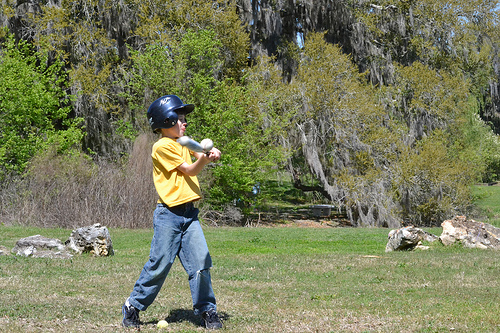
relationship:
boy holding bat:
[123, 94, 223, 331] [178, 136, 216, 162]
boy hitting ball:
[123, 94, 223, 331] [200, 138, 214, 153]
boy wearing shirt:
[123, 94, 223, 331] [151, 137, 204, 208]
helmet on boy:
[147, 96, 195, 134] [123, 94, 223, 331]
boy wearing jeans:
[123, 94, 223, 331] [127, 203, 217, 316]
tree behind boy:
[1, 27, 89, 178] [123, 94, 223, 331]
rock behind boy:
[71, 223, 114, 256] [123, 94, 223, 331]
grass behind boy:
[6, 277, 118, 333] [123, 94, 223, 331]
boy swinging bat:
[123, 94, 223, 331] [178, 136, 216, 162]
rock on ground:
[71, 223, 114, 256] [0, 226, 499, 333]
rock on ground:
[15, 234, 69, 259] [0, 226, 499, 333]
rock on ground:
[440, 215, 499, 249] [0, 226, 499, 333]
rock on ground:
[385, 225, 439, 251] [0, 226, 499, 333]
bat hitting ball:
[178, 136, 216, 162] [200, 138, 214, 153]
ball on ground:
[157, 319, 168, 328] [0, 226, 499, 333]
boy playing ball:
[123, 94, 223, 331] [200, 138, 214, 153]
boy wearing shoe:
[123, 94, 223, 331] [201, 311, 224, 331]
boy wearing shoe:
[123, 94, 223, 331] [124, 300, 141, 327]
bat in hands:
[178, 136, 216, 162] [200, 146, 221, 162]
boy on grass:
[123, 94, 223, 331] [117, 262, 252, 332]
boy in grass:
[123, 94, 223, 331] [117, 262, 252, 332]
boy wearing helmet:
[123, 94, 223, 331] [147, 96, 195, 134]